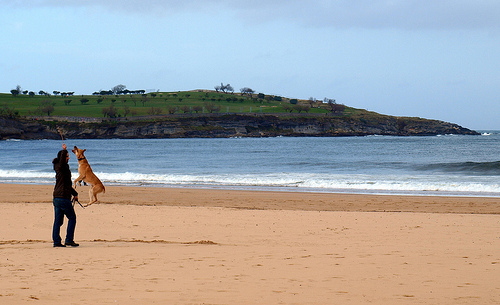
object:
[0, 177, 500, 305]
ground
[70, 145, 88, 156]
head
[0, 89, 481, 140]
hillside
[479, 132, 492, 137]
boat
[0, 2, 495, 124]
sky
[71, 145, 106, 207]
animals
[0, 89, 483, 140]
land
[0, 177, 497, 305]
land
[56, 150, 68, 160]
hair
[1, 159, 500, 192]
wave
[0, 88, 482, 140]
cliff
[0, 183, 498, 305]
beach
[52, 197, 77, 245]
jeans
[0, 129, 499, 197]
water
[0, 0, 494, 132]
cloud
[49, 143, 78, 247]
man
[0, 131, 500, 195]
ocean